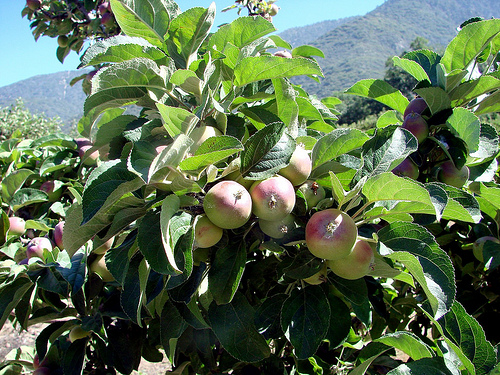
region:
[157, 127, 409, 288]
a bushel of fruit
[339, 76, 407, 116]
a leaf on the bushel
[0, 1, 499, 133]
mountains in the background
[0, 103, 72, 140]
tree in the background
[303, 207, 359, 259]
a red and yellow fruit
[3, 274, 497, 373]
leaves on the bottom of the bush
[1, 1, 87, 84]
blues sky in far background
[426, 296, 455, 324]
tip of the fruit bush leaf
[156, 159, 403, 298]
fruits attached to the tree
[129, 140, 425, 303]
fruits attached to the tree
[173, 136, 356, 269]
fruits attached to the tree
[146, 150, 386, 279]
fruits attached to the tree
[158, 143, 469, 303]
fruits attached to the tree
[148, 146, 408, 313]
the tree has fruits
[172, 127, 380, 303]
the tree has fruits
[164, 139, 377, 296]
the tree has fruits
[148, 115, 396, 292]
the tree has fruits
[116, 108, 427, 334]
the tree has fruits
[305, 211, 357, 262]
fruite is next to fruit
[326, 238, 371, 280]
fruite is next to fruit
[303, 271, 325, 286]
fruite is next to fruit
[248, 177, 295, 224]
fruite is next to fruit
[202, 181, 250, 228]
fruite is next to fruit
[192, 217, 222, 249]
fruite is next to fruit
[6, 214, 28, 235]
fruite is next to fruit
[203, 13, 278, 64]
The leaf is green.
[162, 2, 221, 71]
The leaf is green.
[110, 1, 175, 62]
The leaf is green.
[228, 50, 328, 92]
The leaf is green.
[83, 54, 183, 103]
The leaf is green.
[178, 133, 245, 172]
The leaf is green.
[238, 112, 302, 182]
The leaf is green.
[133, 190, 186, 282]
The leaf is green.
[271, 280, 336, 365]
The leaf is green.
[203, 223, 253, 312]
The leaf is green.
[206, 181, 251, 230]
a peach on a tree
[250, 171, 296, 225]
a peach on a tree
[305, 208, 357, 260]
a peach on a tree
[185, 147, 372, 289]
peaches on a tree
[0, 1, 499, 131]
a hill in the distance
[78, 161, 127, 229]
a dark green leaf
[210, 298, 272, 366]
a leaf in the shade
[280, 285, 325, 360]
a leaf in the shade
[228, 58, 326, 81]
a leaf in the sun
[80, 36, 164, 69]
a leaf in the sun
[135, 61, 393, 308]
there are fruits in the tree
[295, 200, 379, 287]
the fruits are yellow and red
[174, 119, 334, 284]
a bushel of fruits in a tree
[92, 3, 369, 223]
the leaves are bright because of the sun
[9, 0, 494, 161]
there is a mountain covered in vegetation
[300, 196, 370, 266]
the fruits are round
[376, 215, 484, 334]
the leaves are curved and folded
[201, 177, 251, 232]
yellow and read fruit on the tree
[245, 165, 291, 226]
yellow and read fruit on the tree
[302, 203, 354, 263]
yellow and read fruit on the tree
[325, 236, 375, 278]
yellow and read fruit on the tree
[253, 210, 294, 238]
yellow and read fruit on the tree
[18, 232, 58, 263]
yellow and read fruit on the tree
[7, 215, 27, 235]
yellow and read fruit on the tree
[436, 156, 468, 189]
yellow and read fruit on the tree